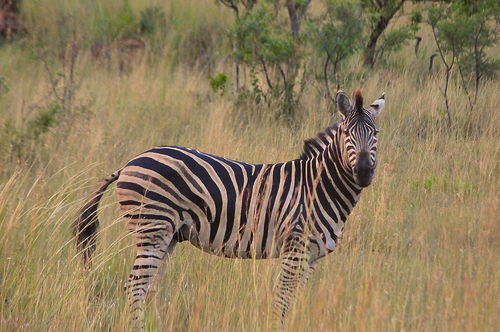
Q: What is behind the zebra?
A: A tree.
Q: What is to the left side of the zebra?
A: Bushes and shrubs.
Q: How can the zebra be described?
A: As black and white.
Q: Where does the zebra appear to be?
A: In a field with high grass.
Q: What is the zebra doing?
A: Standing in a field.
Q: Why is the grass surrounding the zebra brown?
A: It's dry.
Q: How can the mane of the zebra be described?
A: As black and white stripes.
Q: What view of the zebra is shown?
A: A side view.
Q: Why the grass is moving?
A: Wind blowing.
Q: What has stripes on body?
A: Zebra.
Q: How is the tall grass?
A: Dried out.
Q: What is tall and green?
A: Trees.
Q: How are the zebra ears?
A: Standing up.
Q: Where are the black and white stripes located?
A: On the zebra.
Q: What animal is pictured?
A: Zebra.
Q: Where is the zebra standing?
A: On a grassy plain.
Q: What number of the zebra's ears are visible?
A: Two.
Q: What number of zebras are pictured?
A: One.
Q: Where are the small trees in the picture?
A: In the background behind the zebra.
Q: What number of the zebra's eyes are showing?
A: Two.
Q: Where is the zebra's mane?
A: On the head and back of the neck of the zebra.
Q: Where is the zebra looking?
A: Towards the camera.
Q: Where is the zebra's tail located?
A: On the rear end of the zebra.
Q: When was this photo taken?
A: During the daytime.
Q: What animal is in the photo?
A: A zebra.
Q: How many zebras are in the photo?
A: One.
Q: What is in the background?
A: Grass and trees.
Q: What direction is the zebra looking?
A: Toward the camera.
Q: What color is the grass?
A: Yellow and green.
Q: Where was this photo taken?
A: In a field.